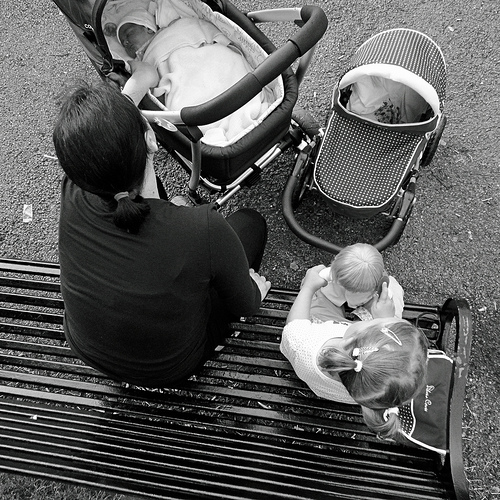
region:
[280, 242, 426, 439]
girl holding a doll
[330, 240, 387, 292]
doll has blonde hair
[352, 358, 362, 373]
hair band in girl's hair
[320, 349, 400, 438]
the girl has ponytails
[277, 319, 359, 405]
the shirt is white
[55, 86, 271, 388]
woman sitting on the bench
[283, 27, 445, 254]
stroller on the ground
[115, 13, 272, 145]
the baby is sleeping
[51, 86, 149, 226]
woman has dark hair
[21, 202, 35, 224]
trash on the ground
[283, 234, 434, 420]
a young girl playing with a doll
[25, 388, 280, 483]
slats on a bench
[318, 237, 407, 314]
the top of a baby doll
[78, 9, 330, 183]
a baby in a carriage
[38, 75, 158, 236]
a woman with dark hair and a ponytail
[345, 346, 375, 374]
the ribbon of a ponytail on a young girl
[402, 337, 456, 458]
the top of a backpack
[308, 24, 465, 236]
a carriage for a baby doll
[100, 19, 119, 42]
a baby's pacifier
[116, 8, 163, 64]
the face of a sleeping baby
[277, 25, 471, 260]
black and white baby carriage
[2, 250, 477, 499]
black metal bench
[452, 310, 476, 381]
marks on bench arm rest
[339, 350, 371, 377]
white ponytail holder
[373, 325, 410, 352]
white barrette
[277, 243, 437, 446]
little girl holding baby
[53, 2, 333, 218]
baby in baby carriage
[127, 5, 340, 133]
handle on baby carriage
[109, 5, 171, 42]
white hat on baby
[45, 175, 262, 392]
black long sleeve shirt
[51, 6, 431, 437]
three people seen from above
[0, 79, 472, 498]
woman is seated on a bench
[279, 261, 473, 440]
girl is seated near armrest of bench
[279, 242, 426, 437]
girl is holding a doll on her lap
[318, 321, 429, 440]
girl's fair hair is pulled up into pigtails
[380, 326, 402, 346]
barrette in girl's hair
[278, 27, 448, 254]
a stroller for a doll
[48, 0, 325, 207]
baby asleep in a stroller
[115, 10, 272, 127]
woman's hand next to baby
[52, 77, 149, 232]
woman's dark hair is pulled into a low ponytail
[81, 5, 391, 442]
two ladies with kids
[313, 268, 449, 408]
lady carying a baby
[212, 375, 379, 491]
the bench is metallic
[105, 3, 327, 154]
baby sleeping in a baby stroller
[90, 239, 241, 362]
blouse is black in color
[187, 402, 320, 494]
bench is black in color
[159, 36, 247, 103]
baby is dressed in white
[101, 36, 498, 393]
background color is black and white